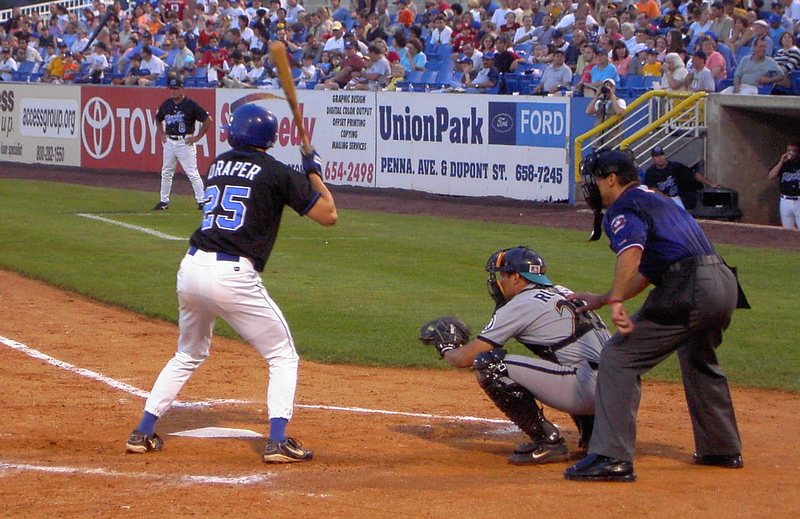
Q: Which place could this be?
A: It is a field.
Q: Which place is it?
A: It is a field.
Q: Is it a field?
A: Yes, it is a field.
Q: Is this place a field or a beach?
A: It is a field.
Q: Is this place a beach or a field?
A: It is a field.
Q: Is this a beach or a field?
A: It is a field.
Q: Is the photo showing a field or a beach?
A: It is showing a field.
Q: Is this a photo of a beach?
A: No, the picture is showing a field.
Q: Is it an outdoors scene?
A: Yes, it is outdoors.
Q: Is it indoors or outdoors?
A: It is outdoors.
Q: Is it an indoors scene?
A: No, it is outdoors.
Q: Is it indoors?
A: No, it is outdoors.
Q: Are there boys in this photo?
A: No, there are no boys.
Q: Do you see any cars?
A: No, there are no cars.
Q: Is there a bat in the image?
A: Yes, there is a bat.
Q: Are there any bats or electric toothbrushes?
A: Yes, there is a bat.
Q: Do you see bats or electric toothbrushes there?
A: Yes, there is a bat.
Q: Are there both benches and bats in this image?
A: No, there is a bat but no benches.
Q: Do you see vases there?
A: No, there are no vases.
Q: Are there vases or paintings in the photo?
A: No, there are no vases or paintings.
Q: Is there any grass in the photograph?
A: Yes, there is grass.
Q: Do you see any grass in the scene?
A: Yes, there is grass.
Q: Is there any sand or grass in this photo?
A: Yes, there is grass.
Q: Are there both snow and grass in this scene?
A: No, there is grass but no snow.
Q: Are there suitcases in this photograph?
A: No, there are no suitcases.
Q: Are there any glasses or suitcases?
A: No, there are no suitcases or glasses.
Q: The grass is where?
A: The grass is in the field.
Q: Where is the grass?
A: The grass is in the field.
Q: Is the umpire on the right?
A: Yes, the umpire is on the right of the image.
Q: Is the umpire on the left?
A: No, the umpire is on the right of the image.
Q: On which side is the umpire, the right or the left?
A: The umpire is on the right of the image.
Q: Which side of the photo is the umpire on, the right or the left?
A: The umpire is on the right of the image.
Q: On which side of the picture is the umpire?
A: The umpire is on the right of the image.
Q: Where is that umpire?
A: The umpire is on the field.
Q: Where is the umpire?
A: The umpire is on the field.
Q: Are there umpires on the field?
A: Yes, there is an umpire on the field.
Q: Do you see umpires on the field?
A: Yes, there is an umpire on the field.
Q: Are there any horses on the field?
A: No, there is an umpire on the field.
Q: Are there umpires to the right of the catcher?
A: Yes, there is an umpire to the right of the catcher.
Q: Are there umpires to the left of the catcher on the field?
A: No, the umpire is to the right of the catcher.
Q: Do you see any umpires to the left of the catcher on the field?
A: No, the umpire is to the right of the catcher.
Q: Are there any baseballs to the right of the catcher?
A: No, there is an umpire to the right of the catcher.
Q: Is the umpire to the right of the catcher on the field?
A: Yes, the umpire is to the right of the catcher.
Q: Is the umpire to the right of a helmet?
A: No, the umpire is to the right of the catcher.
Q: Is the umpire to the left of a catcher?
A: No, the umpire is to the right of a catcher.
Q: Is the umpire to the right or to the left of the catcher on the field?
A: The umpire is to the right of the catcher.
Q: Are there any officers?
A: No, there are no officers.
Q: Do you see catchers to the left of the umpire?
A: Yes, there is a catcher to the left of the umpire.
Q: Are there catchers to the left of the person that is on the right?
A: Yes, there is a catcher to the left of the umpire.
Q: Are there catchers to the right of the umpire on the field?
A: No, the catcher is to the left of the umpire.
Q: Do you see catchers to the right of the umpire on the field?
A: No, the catcher is to the left of the umpire.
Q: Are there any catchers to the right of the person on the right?
A: No, the catcher is to the left of the umpire.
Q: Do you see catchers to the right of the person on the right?
A: No, the catcher is to the left of the umpire.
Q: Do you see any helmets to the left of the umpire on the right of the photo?
A: No, there is a catcher to the left of the umpire.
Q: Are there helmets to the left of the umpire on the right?
A: No, there is a catcher to the left of the umpire.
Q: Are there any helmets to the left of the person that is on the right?
A: No, there is a catcher to the left of the umpire.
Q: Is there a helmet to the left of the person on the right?
A: No, there is a catcher to the left of the umpire.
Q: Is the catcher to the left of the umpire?
A: Yes, the catcher is to the left of the umpire.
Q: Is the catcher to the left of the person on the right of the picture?
A: Yes, the catcher is to the left of the umpire.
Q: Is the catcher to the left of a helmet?
A: No, the catcher is to the left of the umpire.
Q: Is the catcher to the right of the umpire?
A: No, the catcher is to the left of the umpire.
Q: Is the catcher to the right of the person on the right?
A: No, the catcher is to the left of the umpire.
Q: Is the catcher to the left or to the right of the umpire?
A: The catcher is to the left of the umpire.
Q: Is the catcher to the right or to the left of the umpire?
A: The catcher is to the left of the umpire.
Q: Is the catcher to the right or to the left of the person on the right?
A: The catcher is to the left of the umpire.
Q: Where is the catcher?
A: The catcher is on the field.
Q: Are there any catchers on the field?
A: Yes, there is a catcher on the field.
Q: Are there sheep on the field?
A: No, there is a catcher on the field.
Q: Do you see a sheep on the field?
A: No, there is a catcher on the field.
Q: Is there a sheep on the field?
A: No, there is a catcher on the field.